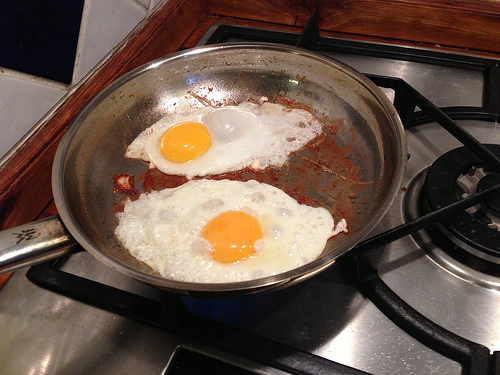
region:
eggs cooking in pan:
[91, 89, 352, 284]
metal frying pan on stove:
[1, 37, 408, 297]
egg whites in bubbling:
[111, 94, 339, 278]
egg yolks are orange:
[158, 122, 260, 260]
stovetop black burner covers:
[29, 4, 499, 371]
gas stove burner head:
[428, 134, 498, 274]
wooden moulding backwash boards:
[1, 4, 498, 295]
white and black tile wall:
[3, 1, 160, 161]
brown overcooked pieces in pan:
[109, 93, 364, 238]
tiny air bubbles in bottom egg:
[141, 194, 297, 261]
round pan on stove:
[44, 20, 409, 304]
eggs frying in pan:
[117, 90, 321, 269]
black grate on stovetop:
[368, 40, 497, 352]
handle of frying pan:
[0, 154, 125, 311]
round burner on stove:
[411, 100, 497, 295]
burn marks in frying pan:
[251, 61, 376, 247]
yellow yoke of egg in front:
[173, 185, 290, 272]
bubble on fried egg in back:
[151, 94, 289, 171]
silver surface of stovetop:
[47, 258, 286, 374]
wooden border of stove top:
[166, 0, 471, 127]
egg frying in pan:
[116, 177, 347, 285]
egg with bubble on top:
[123, 98, 320, 171]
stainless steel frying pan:
[4, 43, 413, 305]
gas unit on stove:
[380, 47, 499, 372]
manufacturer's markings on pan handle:
[10, 223, 40, 243]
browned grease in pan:
[123, 160, 355, 202]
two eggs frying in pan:
[52, 38, 412, 300]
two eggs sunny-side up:
[120, 103, 345, 281]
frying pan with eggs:
[8, 40, 408, 305]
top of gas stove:
[15, 3, 497, 373]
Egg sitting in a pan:
[116, 176, 342, 285]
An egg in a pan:
[126, 95, 325, 176]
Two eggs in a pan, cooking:
[114, 101, 335, 288]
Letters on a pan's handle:
[12, 226, 40, 245]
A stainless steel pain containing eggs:
[1, 43, 404, 297]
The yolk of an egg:
[198, 206, 264, 263]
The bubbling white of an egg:
[216, 104, 295, 161]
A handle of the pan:
[0, 214, 74, 281]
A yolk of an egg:
[156, 117, 215, 162]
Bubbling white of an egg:
[123, 197, 205, 272]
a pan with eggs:
[41, 22, 414, 317]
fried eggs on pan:
[111, 81, 341, 291]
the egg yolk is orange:
[196, 203, 267, 267]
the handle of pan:
[3, 205, 78, 277]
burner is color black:
[18, 21, 498, 373]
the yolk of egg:
[147, 112, 217, 167]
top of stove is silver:
[5, 12, 498, 372]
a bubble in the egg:
[203, 103, 254, 143]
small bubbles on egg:
[123, 182, 298, 284]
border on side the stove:
[0, 3, 499, 250]